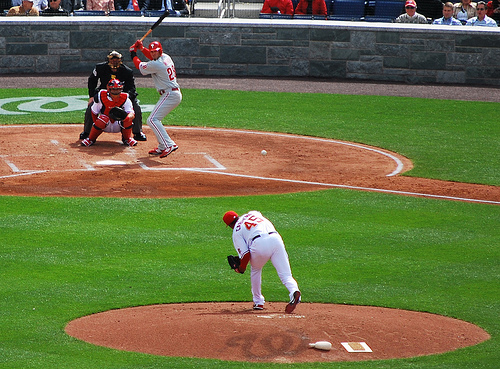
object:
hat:
[221, 211, 241, 227]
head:
[222, 209, 239, 229]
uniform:
[231, 209, 302, 306]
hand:
[225, 255, 241, 274]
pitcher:
[222, 210, 301, 313]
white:
[262, 223, 270, 230]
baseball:
[261, 149, 268, 155]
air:
[233, 139, 249, 155]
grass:
[445, 101, 489, 141]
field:
[0, 88, 497, 369]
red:
[224, 211, 234, 219]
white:
[212, 158, 220, 165]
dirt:
[290, 144, 327, 172]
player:
[129, 39, 183, 158]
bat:
[128, 11, 172, 49]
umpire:
[78, 50, 144, 142]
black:
[99, 67, 108, 73]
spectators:
[394, 0, 500, 28]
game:
[71, 20, 314, 324]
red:
[156, 42, 159, 49]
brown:
[142, 29, 153, 40]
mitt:
[109, 106, 126, 120]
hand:
[134, 40, 143, 49]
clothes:
[87, 61, 139, 100]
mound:
[216, 309, 318, 331]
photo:
[0, 5, 490, 355]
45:
[245, 215, 264, 231]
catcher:
[80, 79, 139, 148]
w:
[230, 326, 308, 360]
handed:
[129, 44, 137, 53]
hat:
[149, 41, 160, 52]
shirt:
[139, 52, 180, 92]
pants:
[147, 92, 183, 151]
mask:
[107, 51, 123, 68]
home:
[96, 160, 127, 166]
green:
[326, 103, 367, 126]